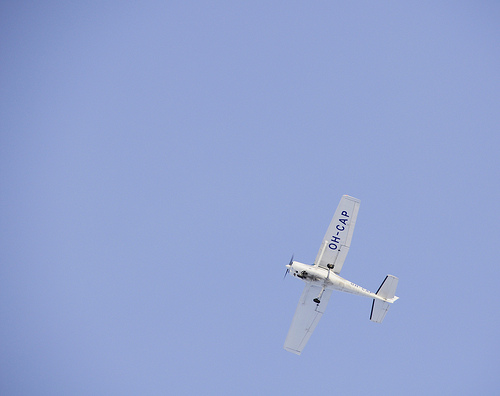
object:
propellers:
[275, 250, 295, 275]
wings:
[281, 194, 360, 357]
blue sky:
[1, 0, 499, 395]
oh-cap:
[329, 210, 350, 250]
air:
[0, 1, 499, 395]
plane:
[281, 193, 401, 356]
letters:
[328, 210, 349, 250]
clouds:
[0, 0, 499, 395]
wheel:
[313, 298, 320, 303]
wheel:
[327, 264, 334, 269]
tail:
[369, 274, 400, 324]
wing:
[313, 194, 362, 273]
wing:
[280, 282, 331, 357]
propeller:
[282, 269, 289, 280]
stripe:
[369, 276, 389, 320]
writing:
[329, 211, 349, 251]